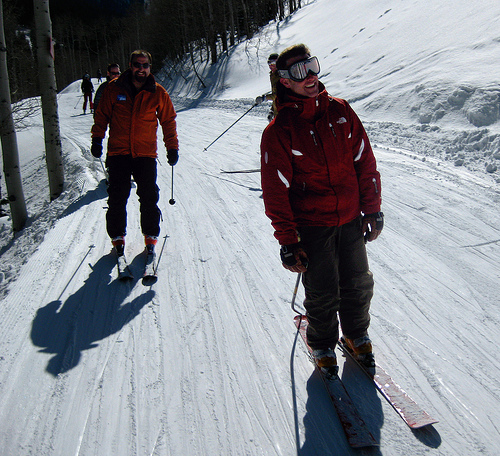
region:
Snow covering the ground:
[11, 391, 63, 451]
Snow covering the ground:
[69, 397, 111, 432]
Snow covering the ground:
[105, 386, 177, 440]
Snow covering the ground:
[182, 404, 260, 444]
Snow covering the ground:
[251, 371, 303, 418]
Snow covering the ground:
[189, 318, 261, 364]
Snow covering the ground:
[108, 304, 154, 339]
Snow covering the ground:
[5, 269, 63, 324]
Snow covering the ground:
[423, 344, 450, 390]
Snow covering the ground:
[403, 278, 456, 332]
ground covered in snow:
[49, 268, 281, 385]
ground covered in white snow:
[33, 291, 235, 448]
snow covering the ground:
[66, 323, 231, 451]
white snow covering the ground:
[39, 320, 143, 448]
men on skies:
[191, 40, 458, 454]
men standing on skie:
[185, 50, 464, 390]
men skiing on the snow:
[239, 14, 492, 398]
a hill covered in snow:
[319, 25, 442, 200]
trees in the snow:
[9, 34, 164, 262]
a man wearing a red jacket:
[155, 52, 440, 443]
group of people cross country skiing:
[21, 20, 474, 432]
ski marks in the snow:
[121, 340, 262, 450]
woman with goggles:
[265, 50, 330, 96]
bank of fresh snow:
[401, 5, 486, 60]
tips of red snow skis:
[325, 395, 435, 451]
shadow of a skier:
[30, 265, 161, 380]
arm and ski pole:
[160, 125, 180, 210]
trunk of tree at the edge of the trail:
[30, 80, 70, 206]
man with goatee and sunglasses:
[125, 46, 152, 86]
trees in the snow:
[161, 0, 283, 58]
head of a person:
[262, 39, 336, 100]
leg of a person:
[252, 162, 316, 247]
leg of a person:
[341, 126, 382, 203]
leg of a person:
[85, 88, 110, 140]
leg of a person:
[145, 88, 185, 149]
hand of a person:
[81, 138, 108, 163]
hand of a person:
[151, 146, 191, 173]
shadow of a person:
[31, 261, 143, 383]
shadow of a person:
[301, 378, 368, 448]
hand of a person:
[277, 235, 319, 266]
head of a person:
[122, 29, 164, 83]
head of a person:
[103, 63, 127, 78]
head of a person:
[79, 68, 97, 85]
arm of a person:
[256, 176, 317, 270]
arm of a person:
[352, 129, 393, 217]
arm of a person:
[85, 89, 119, 139]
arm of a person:
[150, 99, 202, 147]